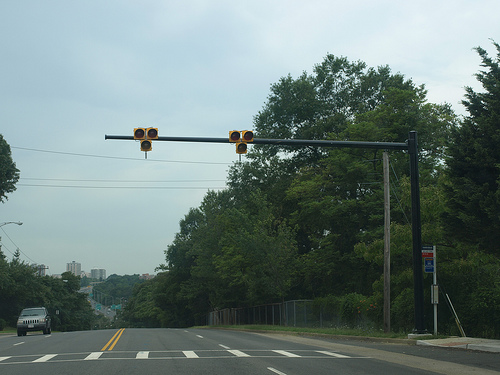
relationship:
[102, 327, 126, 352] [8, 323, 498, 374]
line in street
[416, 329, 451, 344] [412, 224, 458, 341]
base on post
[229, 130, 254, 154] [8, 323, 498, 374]
traffic light across street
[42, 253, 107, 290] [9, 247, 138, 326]
buildings in distance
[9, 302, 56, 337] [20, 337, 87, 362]
car on road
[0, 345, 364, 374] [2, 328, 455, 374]
crossing on road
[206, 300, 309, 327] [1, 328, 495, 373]
fencing near road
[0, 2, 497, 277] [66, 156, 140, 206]
sky with clouds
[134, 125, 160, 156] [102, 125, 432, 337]
light with pole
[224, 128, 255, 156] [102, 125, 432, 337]
light with pole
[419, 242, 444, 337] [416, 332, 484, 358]
sign on sidewalk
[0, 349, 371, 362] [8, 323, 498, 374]
crossing across street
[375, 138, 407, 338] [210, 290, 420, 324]
pole by fence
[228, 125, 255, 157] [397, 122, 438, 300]
traffic light on steel pole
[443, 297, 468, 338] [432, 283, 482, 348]
metal on cords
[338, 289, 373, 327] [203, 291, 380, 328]
plant across fence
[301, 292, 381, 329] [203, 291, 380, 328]
plant across fence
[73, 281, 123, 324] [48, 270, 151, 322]
street through trees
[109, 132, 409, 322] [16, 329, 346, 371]
lightpole over street